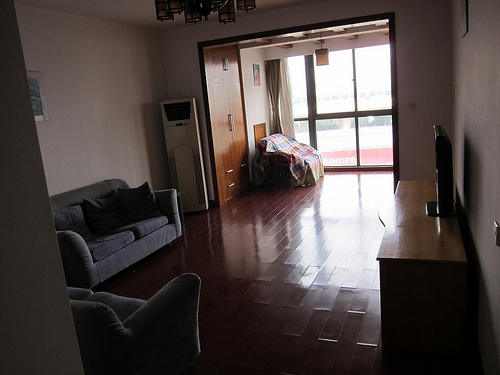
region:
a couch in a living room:
[44, 175, 193, 282]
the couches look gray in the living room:
[47, 174, 201, 374]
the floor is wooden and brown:
[71, 165, 391, 370]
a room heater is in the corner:
[155, 93, 220, 218]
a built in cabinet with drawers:
[205, 41, 255, 202]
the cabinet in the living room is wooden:
[206, 45, 251, 205]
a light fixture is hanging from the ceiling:
[313, 36, 328, 62]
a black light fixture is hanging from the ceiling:
[155, 2, 251, 28]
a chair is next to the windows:
[252, 127, 325, 190]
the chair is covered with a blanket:
[251, 130, 326, 199]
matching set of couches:
[45, 172, 203, 374]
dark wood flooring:
[243, 195, 371, 362]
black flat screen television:
[423, 122, 457, 222]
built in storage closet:
[204, 80, 254, 205]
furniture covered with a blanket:
[257, 128, 327, 189]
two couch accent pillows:
[78, 178, 160, 230]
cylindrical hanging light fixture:
[313, 41, 331, 67]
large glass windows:
[313, 65, 391, 168]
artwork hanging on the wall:
[22, 66, 56, 124]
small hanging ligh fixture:
[150, 0, 261, 27]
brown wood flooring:
[246, 190, 375, 372]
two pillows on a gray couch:
[60, 175, 182, 267]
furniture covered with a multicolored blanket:
[258, 133, 326, 186]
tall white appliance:
[159, 97, 207, 186]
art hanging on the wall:
[26, 65, 60, 118]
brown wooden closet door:
[209, 63, 249, 206]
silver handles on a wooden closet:
[227, 111, 236, 133]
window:
[358, 115, 392, 165]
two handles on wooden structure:
[224, 167, 236, 187]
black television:
[425, 117, 456, 226]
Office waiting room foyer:
[36, 105, 484, 369]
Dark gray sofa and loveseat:
[44, 183, 212, 369]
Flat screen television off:
[419, 105, 461, 254]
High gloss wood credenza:
[369, 173, 486, 364]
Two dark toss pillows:
[77, 183, 169, 230]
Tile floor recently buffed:
[290, 169, 377, 336]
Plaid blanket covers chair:
[257, 128, 329, 193]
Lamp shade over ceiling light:
[312, 39, 339, 78]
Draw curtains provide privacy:
[263, 50, 298, 140]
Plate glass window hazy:
[323, 55, 396, 169]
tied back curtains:
[262, 58, 283, 133]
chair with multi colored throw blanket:
[258, 131, 325, 186]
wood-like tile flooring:
[90, 168, 395, 371]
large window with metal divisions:
[282, 43, 393, 169]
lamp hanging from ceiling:
[314, 37, 330, 66]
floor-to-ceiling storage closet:
[202, 45, 252, 207]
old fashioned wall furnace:
[159, 93, 209, 211]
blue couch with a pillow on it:
[48, 176, 184, 286]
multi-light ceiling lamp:
[151, 1, 257, 27]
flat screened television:
[424, 123, 456, 220]